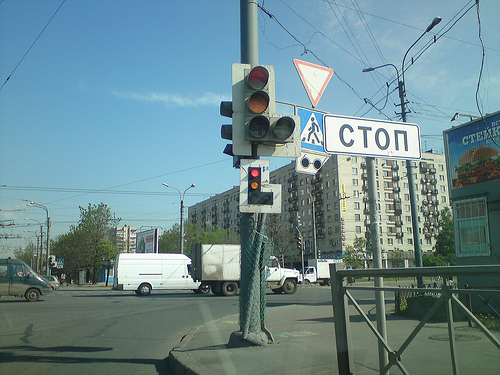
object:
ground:
[0, 280, 499, 374]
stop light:
[238, 158, 282, 213]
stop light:
[219, 101, 232, 119]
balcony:
[364, 209, 396, 216]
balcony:
[365, 232, 398, 239]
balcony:
[364, 219, 396, 227]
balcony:
[363, 198, 395, 204]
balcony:
[367, 186, 394, 193]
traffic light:
[221, 125, 232, 140]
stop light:
[231, 63, 300, 157]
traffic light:
[245, 65, 269, 90]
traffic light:
[271, 116, 295, 140]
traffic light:
[251, 169, 258, 178]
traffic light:
[246, 115, 271, 138]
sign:
[448, 114, 498, 189]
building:
[449, 178, 499, 316]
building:
[187, 152, 453, 280]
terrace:
[287, 184, 297, 193]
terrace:
[288, 207, 298, 213]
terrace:
[316, 230, 324, 239]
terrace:
[312, 206, 322, 213]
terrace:
[310, 190, 322, 196]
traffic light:
[223, 143, 234, 156]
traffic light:
[251, 182, 258, 190]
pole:
[228, 5, 275, 347]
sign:
[292, 58, 333, 108]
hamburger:
[453, 145, 499, 188]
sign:
[293, 105, 331, 156]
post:
[397, 82, 425, 295]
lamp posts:
[34, 203, 50, 275]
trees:
[49, 202, 131, 285]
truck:
[300, 258, 345, 286]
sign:
[322, 114, 422, 161]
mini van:
[0, 257, 54, 301]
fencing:
[239, 222, 275, 330]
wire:
[254, 213, 274, 343]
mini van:
[113, 252, 210, 295]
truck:
[191, 243, 300, 296]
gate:
[328, 262, 499, 374]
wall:
[477, 257, 500, 304]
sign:
[295, 148, 330, 175]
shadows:
[0, 344, 113, 352]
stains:
[93, 317, 122, 337]